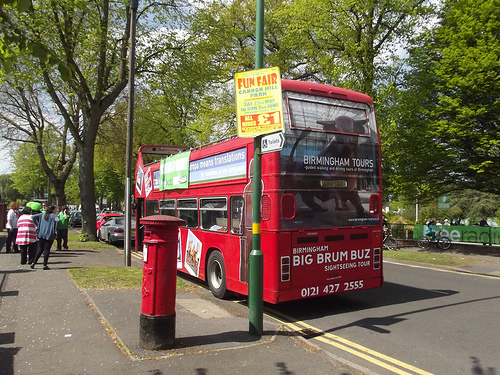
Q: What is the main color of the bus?
A: Red.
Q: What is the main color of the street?
A: Gray.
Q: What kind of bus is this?
A: Double decker.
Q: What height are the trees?
A: Tall.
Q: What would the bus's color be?
A: Red.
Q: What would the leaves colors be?
A: Green and brown.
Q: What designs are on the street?
A: Yellow.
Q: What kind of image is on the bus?
A: An animal.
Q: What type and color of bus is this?
A: A red doubledecker bus.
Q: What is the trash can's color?
A: Red.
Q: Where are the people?
A: On the sidewalk.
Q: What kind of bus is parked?
A: A tourist bus.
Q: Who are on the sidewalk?
A: The tourists.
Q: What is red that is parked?
A: A bus.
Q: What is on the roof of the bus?
A: Seats.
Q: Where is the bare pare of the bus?
A: On the second floor.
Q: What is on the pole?
A: An advertisement.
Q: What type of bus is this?
A: Double decker.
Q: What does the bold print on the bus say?
A: Big brum buz.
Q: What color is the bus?
A: Red.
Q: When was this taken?
A: Daytime.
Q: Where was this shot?
A: Road.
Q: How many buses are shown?
A: 1.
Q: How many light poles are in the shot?
A: 2.